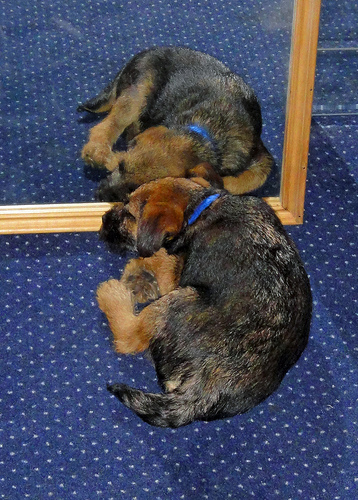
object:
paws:
[121, 257, 158, 310]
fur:
[159, 193, 230, 260]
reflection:
[76, 44, 275, 197]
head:
[100, 177, 208, 255]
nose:
[101, 212, 112, 223]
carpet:
[3, 245, 85, 388]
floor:
[252, 417, 322, 498]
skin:
[222, 145, 262, 187]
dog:
[96, 176, 313, 426]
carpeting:
[2, 0, 120, 128]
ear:
[137, 202, 184, 257]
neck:
[174, 184, 232, 250]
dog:
[76, 47, 275, 193]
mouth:
[100, 207, 134, 247]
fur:
[220, 297, 283, 375]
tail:
[108, 382, 211, 427]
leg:
[97, 279, 142, 355]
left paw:
[120, 252, 168, 301]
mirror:
[1, 1, 294, 202]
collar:
[188, 194, 221, 226]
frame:
[278, 9, 315, 215]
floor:
[0, 258, 100, 497]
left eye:
[123, 207, 135, 221]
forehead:
[129, 187, 147, 213]